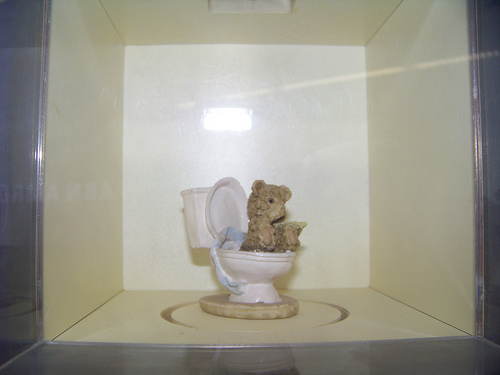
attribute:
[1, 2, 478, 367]
wall — white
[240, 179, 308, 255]
bear — brown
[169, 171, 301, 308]
toilet — miniature, white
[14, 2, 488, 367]
frame — gray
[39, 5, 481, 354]
scene — framed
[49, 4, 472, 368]
walls — yellow